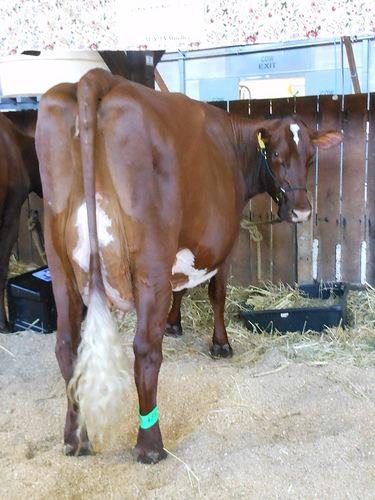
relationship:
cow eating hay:
[67, 75, 331, 251] [259, 271, 311, 310]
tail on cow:
[65, 138, 118, 322] [67, 75, 331, 251]